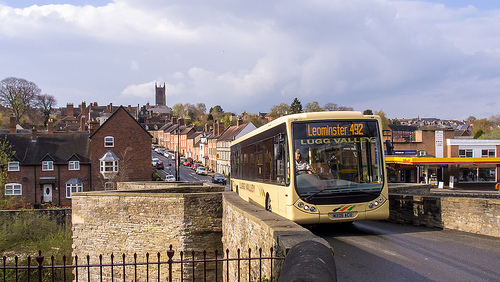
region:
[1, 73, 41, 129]
A tree without leaves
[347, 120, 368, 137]
Bus number 492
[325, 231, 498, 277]
Paved road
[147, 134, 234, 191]
Cars lined up on side of road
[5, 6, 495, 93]
Overcast sky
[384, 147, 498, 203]
A gas station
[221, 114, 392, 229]
Bus traveling across a bridge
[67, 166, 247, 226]
Lookout point in middle of bridge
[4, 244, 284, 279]
Iron safety fence connected to bridge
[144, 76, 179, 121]
Old style church-like building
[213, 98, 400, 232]
bus on a road is yellow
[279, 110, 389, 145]
bus has an electronic display on top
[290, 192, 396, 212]
bus has six headlights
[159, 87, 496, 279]
bus is passing through a bridge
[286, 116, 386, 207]
windshield of bus is large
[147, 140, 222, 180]
cars is seen on street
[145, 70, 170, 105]
a tower of a building in the city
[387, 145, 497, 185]
a gas station below the hill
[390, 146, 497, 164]
roof of gas station is yellow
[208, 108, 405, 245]
Large yellow bus on road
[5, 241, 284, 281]
Wrot iron black fence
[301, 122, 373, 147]
Yellow lettering on front of bus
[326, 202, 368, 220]
Blue, red and green stripes on bus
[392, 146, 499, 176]
Yellow and red top to gas station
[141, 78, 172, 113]
Steeple on top of building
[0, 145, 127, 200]
White windows on building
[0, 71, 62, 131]
Two tall trees above houses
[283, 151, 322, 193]
Man driving a bus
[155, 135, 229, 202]
Cars parked on the street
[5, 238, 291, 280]
a black iron fence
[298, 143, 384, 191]
the front window of a bus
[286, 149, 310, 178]
the driver of a bus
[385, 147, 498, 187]
a yellow and red gas station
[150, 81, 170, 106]
a tower in the distance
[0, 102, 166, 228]
a large red brick building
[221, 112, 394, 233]
a pale yellow bus on a bridg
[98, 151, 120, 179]
a bay window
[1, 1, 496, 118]
a cloudy blue sky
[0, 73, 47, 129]
a bare leafless tree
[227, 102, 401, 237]
a white and blue bus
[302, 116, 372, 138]
an electronic bus destination sign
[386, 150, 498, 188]
a distant gas station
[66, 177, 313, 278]
a stone brick wall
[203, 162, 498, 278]
a small paved bridge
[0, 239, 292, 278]
a wrought iron fence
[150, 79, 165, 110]
a clock tower in distance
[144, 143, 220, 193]
paved road in distance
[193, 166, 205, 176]
a parked car